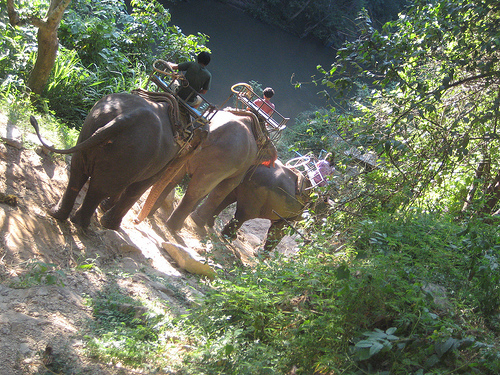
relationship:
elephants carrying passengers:
[31, 91, 329, 253] [168, 51, 335, 189]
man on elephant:
[170, 52, 211, 110] [29, 89, 210, 230]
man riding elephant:
[170, 52, 211, 110] [29, 89, 210, 230]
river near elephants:
[120, 1, 387, 126] [31, 91, 329, 253]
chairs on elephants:
[148, 59, 328, 205] [31, 91, 329, 253]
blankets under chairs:
[132, 84, 316, 201] [148, 59, 328, 205]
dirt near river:
[1, 108, 310, 373] [120, 1, 387, 126]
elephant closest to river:
[208, 159, 332, 260] [120, 1, 387, 126]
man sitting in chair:
[170, 52, 211, 110] [145, 61, 218, 136]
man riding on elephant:
[170, 52, 211, 110] [29, 89, 210, 230]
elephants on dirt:
[31, 91, 329, 253] [1, 108, 310, 373]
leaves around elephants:
[1, 0, 499, 375] [31, 91, 329, 253]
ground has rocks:
[0, 106, 315, 372] [0, 112, 312, 372]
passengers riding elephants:
[168, 51, 335, 189] [31, 91, 329, 253]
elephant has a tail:
[29, 89, 210, 230] [28, 114, 137, 155]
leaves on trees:
[1, 0, 499, 375] [0, 0, 499, 374]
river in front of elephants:
[120, 1, 387, 126] [31, 91, 329, 253]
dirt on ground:
[1, 108, 310, 373] [0, 106, 315, 372]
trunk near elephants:
[6, 1, 72, 107] [31, 91, 329, 253]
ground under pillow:
[0, 106, 315, 372] [161, 241, 217, 277]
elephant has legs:
[29, 89, 210, 230] [46, 157, 164, 231]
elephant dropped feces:
[29, 89, 210, 230] [0, 190, 20, 208]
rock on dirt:
[1, 126, 24, 150] [1, 108, 310, 373]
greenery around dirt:
[0, 1, 498, 374] [1, 108, 310, 373]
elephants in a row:
[31, 91, 329, 253] [29, 48, 338, 256]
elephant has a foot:
[29, 89, 210, 230] [46, 203, 69, 221]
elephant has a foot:
[29, 89, 210, 230] [70, 209, 92, 230]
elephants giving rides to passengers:
[31, 91, 329, 253] [168, 51, 335, 189]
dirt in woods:
[1, 108, 310, 373] [0, 0, 499, 375]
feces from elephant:
[0, 190, 20, 208] [29, 89, 210, 230]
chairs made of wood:
[148, 59, 328, 205] [146, 64, 327, 197]